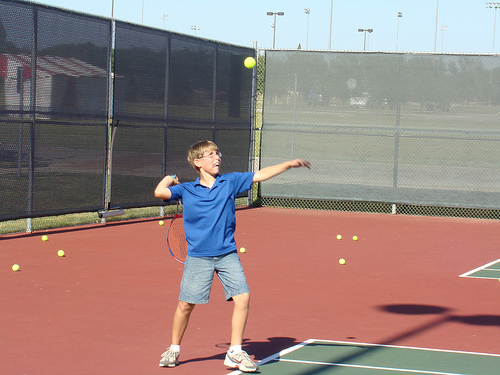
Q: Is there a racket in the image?
A: Yes, there is a racket.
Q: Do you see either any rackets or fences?
A: Yes, there is a racket.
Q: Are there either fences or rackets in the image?
A: Yes, there is a racket.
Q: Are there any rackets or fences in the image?
A: Yes, there is a racket.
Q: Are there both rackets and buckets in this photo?
A: No, there is a racket but no buckets.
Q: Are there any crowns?
A: No, there are no crowns.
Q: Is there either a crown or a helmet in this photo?
A: No, there are no crowns or helmets.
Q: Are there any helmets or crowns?
A: No, there are no crowns or helmets.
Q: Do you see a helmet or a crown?
A: No, there are no crowns or helmets.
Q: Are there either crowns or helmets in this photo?
A: No, there are no crowns or helmets.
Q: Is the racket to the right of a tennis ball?
A: No, the racket is to the left of a tennis ball.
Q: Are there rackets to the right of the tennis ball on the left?
A: Yes, there is a racket to the right of the tennis ball.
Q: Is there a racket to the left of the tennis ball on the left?
A: No, the racket is to the right of the tennis ball.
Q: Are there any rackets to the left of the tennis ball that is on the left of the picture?
A: No, the racket is to the right of the tennis ball.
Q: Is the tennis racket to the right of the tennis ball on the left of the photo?
A: Yes, the tennis racket is to the right of the tennis ball.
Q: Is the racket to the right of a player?
A: No, the racket is to the right of the tennis ball.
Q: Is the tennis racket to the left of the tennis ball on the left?
A: No, the tennis racket is to the right of the tennis ball.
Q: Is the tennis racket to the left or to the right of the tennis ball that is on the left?
A: The tennis racket is to the right of the tennis ball.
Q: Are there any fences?
A: Yes, there is a fence.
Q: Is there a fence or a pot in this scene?
A: Yes, there is a fence.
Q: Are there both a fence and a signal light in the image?
A: No, there is a fence but no traffic lights.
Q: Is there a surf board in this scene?
A: No, there are no surfboards.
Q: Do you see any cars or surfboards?
A: No, there are no surfboards or cars.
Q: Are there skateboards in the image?
A: No, there are no skateboards.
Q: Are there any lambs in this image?
A: Yes, there is a lamb.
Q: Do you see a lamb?
A: Yes, there is a lamb.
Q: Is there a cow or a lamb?
A: Yes, there is a lamb.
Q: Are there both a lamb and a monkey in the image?
A: No, there is a lamb but no monkeys.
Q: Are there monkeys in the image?
A: No, there are no monkeys.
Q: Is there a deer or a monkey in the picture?
A: No, there are no monkeys or deer.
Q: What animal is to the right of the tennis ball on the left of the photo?
A: The animal is a lamb.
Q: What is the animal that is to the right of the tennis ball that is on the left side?
A: The animal is a lamb.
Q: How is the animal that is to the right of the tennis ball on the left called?
A: The animal is a lamb.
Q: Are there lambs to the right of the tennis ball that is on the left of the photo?
A: Yes, there is a lamb to the right of the tennis ball.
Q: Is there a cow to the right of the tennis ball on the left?
A: No, there is a lamb to the right of the tennis ball.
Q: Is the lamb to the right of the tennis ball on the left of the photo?
A: Yes, the lamb is to the right of the tennis ball.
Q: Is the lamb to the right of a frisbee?
A: No, the lamb is to the right of the tennis ball.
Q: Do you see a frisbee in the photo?
A: No, there are no frisbees.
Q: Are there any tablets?
A: No, there are no tablets.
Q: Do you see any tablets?
A: No, there are no tablets.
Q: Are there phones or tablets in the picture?
A: No, there are no tablets or phones.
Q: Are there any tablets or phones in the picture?
A: No, there are no tablets or phones.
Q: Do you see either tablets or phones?
A: No, there are no tablets or phones.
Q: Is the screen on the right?
A: No, the screen is on the left of the image.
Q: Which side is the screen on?
A: The screen is on the left of the image.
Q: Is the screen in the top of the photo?
A: Yes, the screen is in the top of the image.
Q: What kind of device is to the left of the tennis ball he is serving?
A: The device is a screen.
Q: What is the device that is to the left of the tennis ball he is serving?
A: The device is a screen.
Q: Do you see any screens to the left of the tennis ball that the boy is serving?
A: Yes, there is a screen to the left of the tennis ball.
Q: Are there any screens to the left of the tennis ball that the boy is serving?
A: Yes, there is a screen to the left of the tennis ball.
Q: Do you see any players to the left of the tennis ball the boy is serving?
A: No, there is a screen to the left of the tennis ball.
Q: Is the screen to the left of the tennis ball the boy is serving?
A: Yes, the screen is to the left of the tennis ball.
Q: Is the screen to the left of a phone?
A: No, the screen is to the left of the tennis ball.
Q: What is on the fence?
A: The screen is on the fence.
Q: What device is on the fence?
A: The device is a screen.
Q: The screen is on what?
A: The screen is on the fence.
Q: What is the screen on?
A: The screen is on the fence.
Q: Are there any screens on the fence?
A: Yes, there is a screen on the fence.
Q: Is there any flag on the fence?
A: No, there is a screen on the fence.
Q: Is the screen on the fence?
A: Yes, the screen is on the fence.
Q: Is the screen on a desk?
A: No, the screen is on the fence.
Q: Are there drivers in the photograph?
A: No, there are no drivers.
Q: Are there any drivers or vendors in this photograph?
A: No, there are no drivers or vendors.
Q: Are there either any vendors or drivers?
A: No, there are no drivers or vendors.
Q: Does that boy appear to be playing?
A: Yes, the boy is playing.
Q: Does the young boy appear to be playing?
A: Yes, the boy is playing.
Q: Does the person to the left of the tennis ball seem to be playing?
A: Yes, the boy is playing.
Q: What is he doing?
A: The boy is playing.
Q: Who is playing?
A: The boy is playing.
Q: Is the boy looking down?
A: No, the boy is playing.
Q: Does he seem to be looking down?
A: No, the boy is playing.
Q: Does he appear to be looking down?
A: No, the boy is playing.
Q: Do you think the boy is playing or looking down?
A: The boy is playing.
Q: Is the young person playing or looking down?
A: The boy is playing.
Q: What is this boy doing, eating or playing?
A: The boy is playing.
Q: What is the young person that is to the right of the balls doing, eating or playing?
A: The boy is playing.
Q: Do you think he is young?
A: Yes, the boy is young.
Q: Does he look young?
A: Yes, the boy is young.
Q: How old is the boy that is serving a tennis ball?
A: The boy is young.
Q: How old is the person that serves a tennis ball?
A: The boy is young.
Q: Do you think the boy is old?
A: No, the boy is young.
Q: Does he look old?
A: No, the boy is young.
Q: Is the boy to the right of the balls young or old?
A: The boy is young.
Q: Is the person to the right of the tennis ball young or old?
A: The boy is young.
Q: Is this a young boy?
A: Yes, this is a young boy.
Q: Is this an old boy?
A: No, this is a young boy.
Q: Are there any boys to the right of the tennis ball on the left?
A: Yes, there is a boy to the right of the tennis ball.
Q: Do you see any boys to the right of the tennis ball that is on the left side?
A: Yes, there is a boy to the right of the tennis ball.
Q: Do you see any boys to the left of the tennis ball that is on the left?
A: No, the boy is to the right of the tennis ball.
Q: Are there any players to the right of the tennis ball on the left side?
A: No, there is a boy to the right of the tennis ball.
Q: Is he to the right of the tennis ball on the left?
A: Yes, the boy is to the right of the tennis ball.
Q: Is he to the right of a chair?
A: No, the boy is to the right of the tennis ball.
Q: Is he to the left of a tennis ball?
A: No, the boy is to the right of a tennis ball.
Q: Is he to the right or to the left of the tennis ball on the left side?
A: The boy is to the right of the tennis ball.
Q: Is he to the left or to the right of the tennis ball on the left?
A: The boy is to the right of the tennis ball.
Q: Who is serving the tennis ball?
A: The boy is serving the tennis ball.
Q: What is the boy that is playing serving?
A: The boy is serving a tennis ball.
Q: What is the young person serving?
A: The boy is serving a tennis ball.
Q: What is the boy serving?
A: The boy is serving a tennis ball.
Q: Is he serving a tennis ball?
A: Yes, the boy is serving a tennis ball.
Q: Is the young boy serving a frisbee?
A: No, the boy is serving a tennis ball.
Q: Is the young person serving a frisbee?
A: No, the boy is serving a tennis ball.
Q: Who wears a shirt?
A: The boy wears a shirt.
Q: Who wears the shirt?
A: The boy wears a shirt.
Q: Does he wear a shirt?
A: Yes, the boy wears a shirt.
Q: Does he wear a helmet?
A: No, the boy wears a shirt.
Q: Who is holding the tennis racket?
A: The boy is holding the tennis racket.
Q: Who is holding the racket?
A: The boy is holding the tennis racket.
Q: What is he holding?
A: The boy is holding the racket.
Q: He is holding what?
A: The boy is holding the racket.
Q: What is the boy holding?
A: The boy is holding the racket.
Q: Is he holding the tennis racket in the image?
A: Yes, the boy is holding the tennis racket.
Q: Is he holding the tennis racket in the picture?
A: Yes, the boy is holding the tennis racket.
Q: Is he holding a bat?
A: No, the boy is holding the tennis racket.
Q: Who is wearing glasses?
A: The boy is wearing glasses.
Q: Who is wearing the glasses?
A: The boy is wearing glasses.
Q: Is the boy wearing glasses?
A: Yes, the boy is wearing glasses.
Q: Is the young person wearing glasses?
A: Yes, the boy is wearing glasses.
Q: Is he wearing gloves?
A: No, the boy is wearing glasses.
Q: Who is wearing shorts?
A: The boy is wearing shorts.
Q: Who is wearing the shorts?
A: The boy is wearing shorts.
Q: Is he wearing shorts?
A: Yes, the boy is wearing shorts.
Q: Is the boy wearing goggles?
A: No, the boy is wearing shorts.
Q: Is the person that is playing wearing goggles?
A: No, the boy is wearing shorts.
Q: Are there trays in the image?
A: No, there are no trays.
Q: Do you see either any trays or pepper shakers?
A: No, there are no trays or pepper shakers.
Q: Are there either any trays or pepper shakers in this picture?
A: No, there are no trays or pepper shakers.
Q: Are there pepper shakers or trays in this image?
A: No, there are no trays or pepper shakers.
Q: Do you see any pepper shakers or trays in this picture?
A: No, there are no trays or pepper shakers.